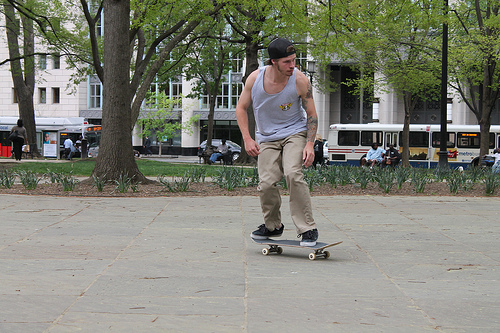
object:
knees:
[284, 168, 308, 184]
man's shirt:
[248, 65, 308, 144]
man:
[234, 37, 319, 247]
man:
[63, 136, 74, 160]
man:
[361, 142, 387, 170]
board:
[251, 236, 343, 252]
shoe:
[295, 227, 320, 247]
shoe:
[249, 223, 286, 240]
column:
[179, 63, 201, 155]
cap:
[266, 36, 297, 66]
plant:
[88, 168, 109, 194]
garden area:
[0, 159, 499, 196]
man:
[379, 143, 401, 171]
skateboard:
[249, 234, 343, 261]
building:
[0, 0, 499, 156]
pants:
[253, 128, 318, 236]